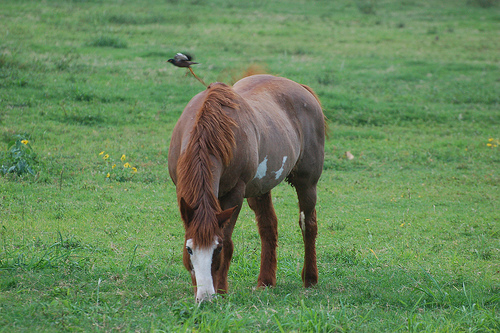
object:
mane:
[190, 84, 240, 172]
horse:
[166, 74, 328, 304]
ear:
[215, 204, 238, 227]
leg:
[248, 191, 278, 287]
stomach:
[246, 172, 288, 195]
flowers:
[18, 136, 30, 148]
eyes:
[182, 245, 195, 255]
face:
[185, 216, 223, 300]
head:
[179, 195, 239, 310]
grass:
[0, 0, 500, 333]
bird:
[165, 52, 198, 67]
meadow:
[0, 0, 500, 331]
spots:
[251, 154, 271, 180]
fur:
[178, 80, 229, 239]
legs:
[295, 182, 318, 287]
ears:
[179, 197, 195, 225]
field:
[0, 0, 500, 333]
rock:
[346, 151, 358, 161]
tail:
[300, 82, 331, 138]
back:
[239, 65, 300, 116]